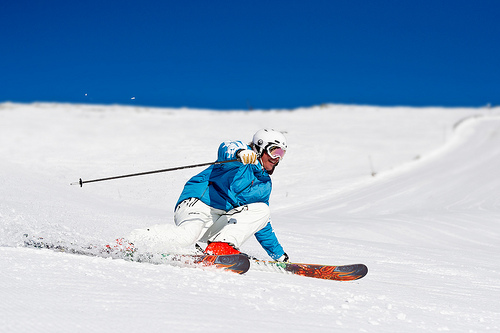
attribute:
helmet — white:
[251, 127, 288, 152]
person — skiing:
[109, 127, 292, 264]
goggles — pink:
[265, 144, 287, 161]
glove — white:
[237, 148, 260, 167]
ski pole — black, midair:
[69, 151, 262, 187]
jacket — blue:
[174, 139, 285, 262]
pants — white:
[122, 196, 272, 252]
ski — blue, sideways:
[249, 255, 370, 280]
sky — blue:
[0, 0, 499, 110]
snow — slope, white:
[1, 102, 499, 331]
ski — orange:
[23, 233, 251, 275]